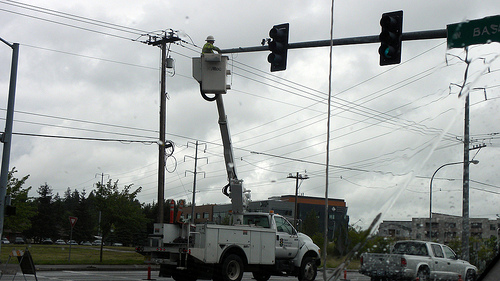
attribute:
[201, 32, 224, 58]
man — fixing light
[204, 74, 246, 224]
crane — white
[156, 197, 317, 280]
truck — white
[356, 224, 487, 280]
pickup — gray, in front of crane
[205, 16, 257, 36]
sky — gray, cloudy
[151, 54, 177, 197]
street pole — brown, on left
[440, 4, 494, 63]
street sign — green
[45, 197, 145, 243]
trees — green, in background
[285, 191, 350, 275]
buildings — brown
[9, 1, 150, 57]
wires — black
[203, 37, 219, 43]
hat — hard, white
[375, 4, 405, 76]
traffic light — banked, double, black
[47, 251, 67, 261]
grass — green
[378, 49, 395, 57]
light — green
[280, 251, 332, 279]
tires — gray, black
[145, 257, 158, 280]
cones — white, orange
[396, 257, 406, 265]
tail light — red